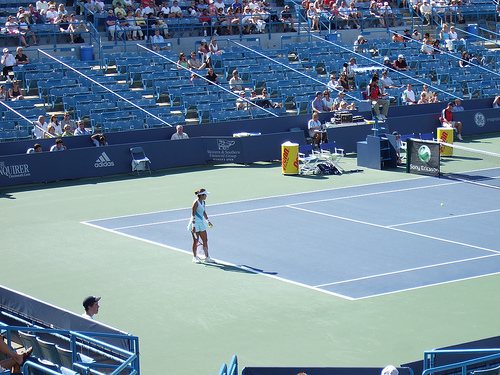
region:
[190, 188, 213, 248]
THAT IS A PERSON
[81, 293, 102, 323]
THAT IS A PERSON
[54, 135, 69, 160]
THAT IS A PERSON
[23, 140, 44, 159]
THAT IS A PERSON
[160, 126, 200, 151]
THAT IS A PERSON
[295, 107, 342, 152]
THAT IS A PERSON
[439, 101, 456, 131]
THAT IS A PERSON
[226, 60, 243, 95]
THAT IS A PERSON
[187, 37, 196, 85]
THAT IS A PERSON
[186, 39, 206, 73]
THAT IS A PERSON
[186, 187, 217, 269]
tennis player standing on court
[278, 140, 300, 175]
large yellow can with penn written on it in red letters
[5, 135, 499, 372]
blue and green tennis court floor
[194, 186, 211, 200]
white sunvisor on head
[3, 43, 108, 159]
spectators sitting in the stands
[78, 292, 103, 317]
ball boy with black cap on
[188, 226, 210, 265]
hot pink tennis racket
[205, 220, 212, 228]
yellow tennis ball in hand?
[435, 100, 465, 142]
man in red jacket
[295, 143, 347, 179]
white chairs stacked in a row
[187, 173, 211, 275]
THAT IS A PERSON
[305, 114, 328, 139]
THAT IS A PERSON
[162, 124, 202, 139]
THAT IS A PERSON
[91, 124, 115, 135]
THAT IS A PERSON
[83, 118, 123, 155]
THAT IS A PERSON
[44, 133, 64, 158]
THAT IS A PERSON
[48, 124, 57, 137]
THAT IS A PERSON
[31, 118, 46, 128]
THAT IS A PERSON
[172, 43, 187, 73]
THAT IS A PERSON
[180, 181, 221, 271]
A female tennis player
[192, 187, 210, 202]
the tennis player's head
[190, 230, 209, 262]
the tennis player's racket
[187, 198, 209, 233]
the tennis player's white dress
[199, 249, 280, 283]
the tennis player's shadow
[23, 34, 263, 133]
Empty blue seats overlooking the tennis court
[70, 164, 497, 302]
the blue tennis court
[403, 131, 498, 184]
the net on the court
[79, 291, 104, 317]
an onlooker on the court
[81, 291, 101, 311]
the onlooker's cap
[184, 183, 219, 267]
A tennis player on a tennis court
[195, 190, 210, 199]
the tennis player's white visor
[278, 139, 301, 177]
A yellow drink cooler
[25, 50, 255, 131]
Blue empty seats overlooking the court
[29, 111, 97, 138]
Six spectators watching the tennis match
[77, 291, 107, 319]
An onlooker on the court